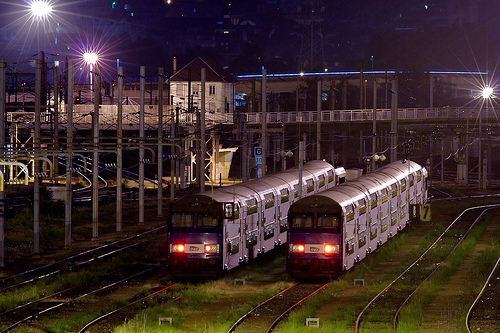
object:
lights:
[298, 245, 305, 252]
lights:
[206, 246, 212, 252]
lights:
[32, 3, 101, 67]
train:
[281, 159, 427, 282]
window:
[264, 192, 275, 210]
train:
[166, 159, 337, 278]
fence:
[0, 49, 500, 266]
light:
[83, 52, 99, 64]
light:
[30, 1, 52, 15]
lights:
[237, 70, 488, 74]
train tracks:
[1, 183, 500, 333]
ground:
[0, 180, 500, 333]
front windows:
[172, 213, 194, 227]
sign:
[420, 204, 432, 221]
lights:
[177, 244, 184, 252]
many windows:
[345, 170, 422, 225]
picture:
[0, 0, 500, 333]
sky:
[0, 0, 500, 90]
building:
[165, 56, 236, 125]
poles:
[32, 53, 164, 260]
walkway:
[7, 105, 500, 123]